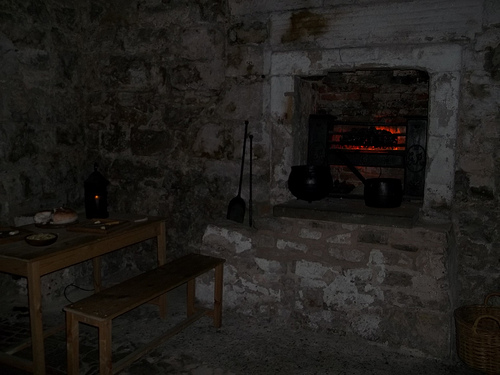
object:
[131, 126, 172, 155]
block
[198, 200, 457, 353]
hearth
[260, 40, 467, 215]
mantle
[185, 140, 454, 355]
mantle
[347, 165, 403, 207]
pot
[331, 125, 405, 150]
fire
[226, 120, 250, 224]
scooper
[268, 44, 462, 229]
fireplace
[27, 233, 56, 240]
food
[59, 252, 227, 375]
bench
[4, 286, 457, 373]
floor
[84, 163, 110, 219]
lantern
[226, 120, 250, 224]
shovel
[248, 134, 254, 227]
poker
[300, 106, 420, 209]
stove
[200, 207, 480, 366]
wall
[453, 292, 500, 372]
basket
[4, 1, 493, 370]
room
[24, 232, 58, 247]
bowl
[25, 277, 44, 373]
leg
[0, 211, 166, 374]
long table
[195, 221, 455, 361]
block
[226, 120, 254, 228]
black untensil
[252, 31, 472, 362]
stone firebplace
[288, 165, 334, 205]
cast iron pot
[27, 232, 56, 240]
food on table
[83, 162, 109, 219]
black latern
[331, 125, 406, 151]
fire place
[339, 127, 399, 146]
food cooking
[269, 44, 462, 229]
brick mantle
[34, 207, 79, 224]
bread plate